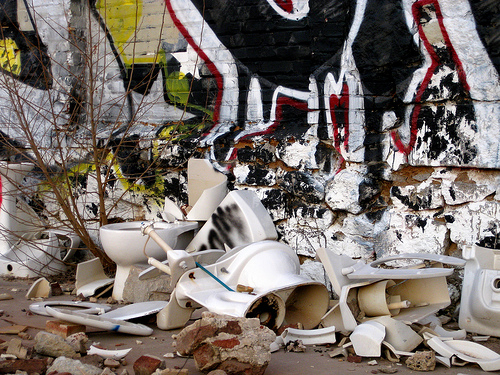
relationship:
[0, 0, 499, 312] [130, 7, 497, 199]
graffiti on wall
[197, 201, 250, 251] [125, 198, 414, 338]
graffiti on toilet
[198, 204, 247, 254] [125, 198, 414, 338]
mom on toilet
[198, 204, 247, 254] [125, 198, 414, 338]
mom spray painted on toilet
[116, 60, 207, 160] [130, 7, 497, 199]
star spray painted on wall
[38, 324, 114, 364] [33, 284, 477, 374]
rock on ground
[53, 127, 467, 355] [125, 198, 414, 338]
graffiti on toilet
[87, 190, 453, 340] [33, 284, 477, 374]
urinal on ground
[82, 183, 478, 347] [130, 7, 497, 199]
graffiti on wall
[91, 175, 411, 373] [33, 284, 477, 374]
seat on ground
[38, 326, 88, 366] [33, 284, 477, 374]
rock on ground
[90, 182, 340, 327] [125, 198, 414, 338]
paint on toilet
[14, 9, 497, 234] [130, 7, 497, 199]
painting on wall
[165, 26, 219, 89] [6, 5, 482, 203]
star on wall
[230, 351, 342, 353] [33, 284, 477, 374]
cement on ground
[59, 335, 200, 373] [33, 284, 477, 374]
brick on ground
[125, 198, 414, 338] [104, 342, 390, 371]
toilet on ground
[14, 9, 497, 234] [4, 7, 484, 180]
painting on wall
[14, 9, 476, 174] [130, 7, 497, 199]
painting on wall